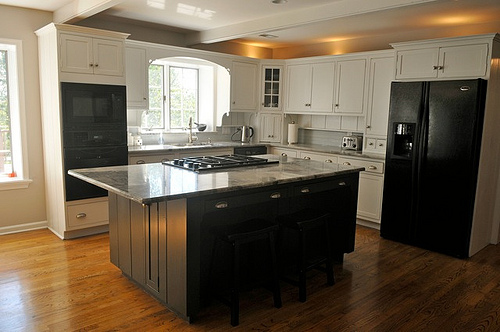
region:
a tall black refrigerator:
[382, 78, 484, 259]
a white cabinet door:
[333, 62, 364, 115]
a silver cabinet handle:
[212, 199, 229, 209]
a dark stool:
[212, 215, 294, 325]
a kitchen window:
[138, 65, 202, 131]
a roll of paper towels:
[285, 119, 297, 144]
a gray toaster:
[340, 133, 360, 150]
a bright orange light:
[240, 37, 260, 57]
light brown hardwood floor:
[0, 225, 185, 328]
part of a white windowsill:
[1, 175, 32, 190]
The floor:
[393, 304, 433, 321]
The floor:
[366, 268, 428, 328]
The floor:
[382, 296, 407, 328]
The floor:
[413, 289, 462, 329]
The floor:
[362, 288, 401, 326]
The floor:
[365, 303, 381, 328]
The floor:
[364, 279, 414, 302]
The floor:
[373, 257, 474, 329]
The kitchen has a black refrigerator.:
[373, 68, 498, 264]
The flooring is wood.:
[10, 244, 122, 329]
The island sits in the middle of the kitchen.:
[90, 152, 381, 302]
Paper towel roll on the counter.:
[283, 113, 304, 153]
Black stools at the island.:
[209, 201, 368, 303]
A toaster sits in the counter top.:
[344, 123, 374, 155]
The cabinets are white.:
[286, 65, 424, 119]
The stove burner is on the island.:
[177, 151, 257, 184]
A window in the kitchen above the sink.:
[146, 65, 208, 127]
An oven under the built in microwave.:
[59, 88, 136, 194]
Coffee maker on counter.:
[233, 123, 255, 143]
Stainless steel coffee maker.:
[235, 121, 255, 143]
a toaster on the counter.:
[339, 131, 364, 152]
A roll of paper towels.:
[286, 118, 298, 146]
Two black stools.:
[211, 210, 337, 322]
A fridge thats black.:
[379, 80, 470, 247]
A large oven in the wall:
[62, 130, 130, 199]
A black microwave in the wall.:
[65, 80, 125, 130]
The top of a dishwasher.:
[234, 145, 265, 154]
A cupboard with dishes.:
[262, 65, 279, 108]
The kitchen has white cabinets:
[40, 12, 487, 262]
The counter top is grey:
[63, 162, 361, 207]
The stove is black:
[169, 144, 260, 184]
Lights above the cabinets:
[236, 30, 483, 75]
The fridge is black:
[374, 67, 481, 281]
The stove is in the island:
[162, 138, 272, 193]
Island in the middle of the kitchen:
[78, 133, 400, 310]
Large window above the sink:
[121, 40, 240, 142]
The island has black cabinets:
[87, 125, 359, 309]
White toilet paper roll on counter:
[282, 111, 299, 151]